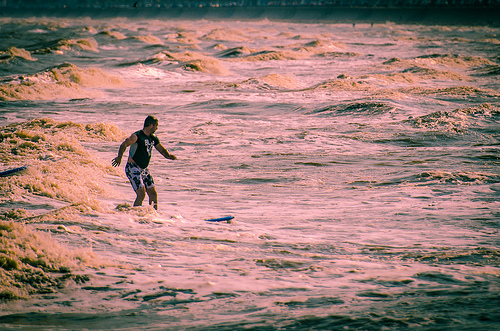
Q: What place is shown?
A: It is an ocean.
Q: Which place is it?
A: It is an ocean.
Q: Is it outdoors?
A: Yes, it is outdoors.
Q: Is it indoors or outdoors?
A: It is outdoors.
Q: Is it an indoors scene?
A: No, it is outdoors.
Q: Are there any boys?
A: No, there are no boys.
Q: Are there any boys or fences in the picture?
A: No, there are no boys or fences.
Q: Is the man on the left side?
A: Yes, the man is on the left of the image.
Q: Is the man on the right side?
A: No, the man is on the left of the image.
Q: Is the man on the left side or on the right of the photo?
A: The man is on the left of the image.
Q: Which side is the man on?
A: The man is on the left of the image.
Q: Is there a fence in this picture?
A: No, there are no fences.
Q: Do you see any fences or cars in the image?
A: No, there are no fences or cars.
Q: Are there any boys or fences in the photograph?
A: No, there are no fences or boys.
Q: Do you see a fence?
A: No, there are no fences.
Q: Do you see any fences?
A: No, there are no fences.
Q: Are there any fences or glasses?
A: No, there are no fences or glasses.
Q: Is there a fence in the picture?
A: No, there are no fences.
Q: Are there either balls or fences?
A: No, there are no fences or balls.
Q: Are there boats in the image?
A: No, there are no boats.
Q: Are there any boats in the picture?
A: No, there are no boats.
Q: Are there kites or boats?
A: No, there are no boats or kites.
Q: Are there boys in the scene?
A: No, there are no boys.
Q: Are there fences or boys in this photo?
A: No, there are no boys or fences.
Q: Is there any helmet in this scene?
A: No, there are no helmets.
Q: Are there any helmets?
A: No, there are no helmets.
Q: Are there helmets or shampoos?
A: No, there are no helmets or shampoos.